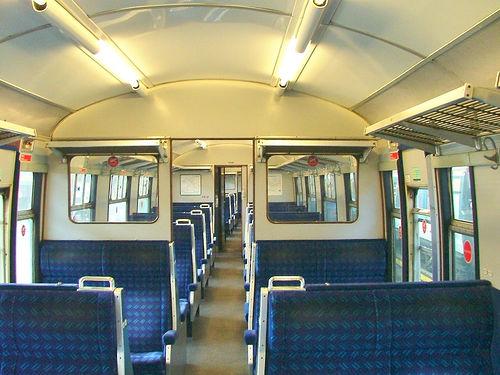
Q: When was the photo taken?
A: Daytime.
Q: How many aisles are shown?
A: One.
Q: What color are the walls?
A: White.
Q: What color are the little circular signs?
A: Red.